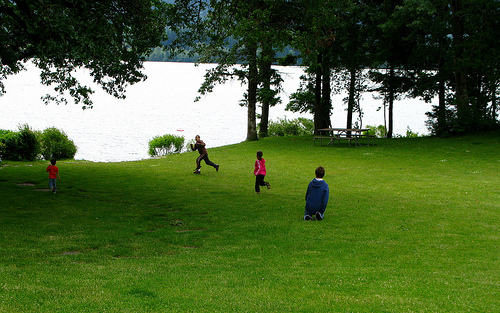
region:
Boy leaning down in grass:
[299, 157, 335, 229]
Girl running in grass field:
[246, 146, 279, 207]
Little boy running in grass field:
[39, 156, 70, 203]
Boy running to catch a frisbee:
[166, 124, 231, 188]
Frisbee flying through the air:
[171, 123, 190, 137]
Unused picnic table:
[310, 116, 379, 153]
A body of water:
[0, 53, 498, 163]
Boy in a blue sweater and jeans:
[300, 156, 330, 236]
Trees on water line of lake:
[202, 0, 498, 153]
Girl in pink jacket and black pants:
[240, 143, 290, 217]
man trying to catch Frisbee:
[158, 116, 226, 211]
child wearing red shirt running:
[33, 148, 89, 220]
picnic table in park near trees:
[305, 111, 417, 166]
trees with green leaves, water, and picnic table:
[217, 78, 455, 150]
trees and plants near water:
[8, 16, 133, 148]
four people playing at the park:
[22, 114, 359, 252]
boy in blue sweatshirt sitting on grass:
[298, 166, 343, 241]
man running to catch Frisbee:
[167, 113, 224, 190]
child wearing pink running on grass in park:
[241, 146, 273, 216]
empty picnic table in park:
[313, 113, 405, 160]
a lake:
[0, 38, 477, 150]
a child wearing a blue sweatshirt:
[287, 141, 342, 236]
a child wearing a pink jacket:
[243, 138, 288, 216]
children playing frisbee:
[158, 119, 299, 217]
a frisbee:
[168, 115, 200, 138]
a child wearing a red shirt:
[31, 131, 101, 208]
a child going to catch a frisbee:
[164, 116, 268, 222]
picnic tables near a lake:
[291, 105, 403, 160]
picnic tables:
[304, 104, 389, 159]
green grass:
[16, 137, 496, 282]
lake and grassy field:
[32, 26, 400, 282]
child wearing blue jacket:
[294, 155, 359, 241]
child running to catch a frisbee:
[160, 103, 229, 188]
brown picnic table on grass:
[301, 108, 401, 158]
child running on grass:
[38, 148, 80, 228]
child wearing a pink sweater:
[230, 134, 286, 211]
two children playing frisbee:
[168, 111, 283, 208]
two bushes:
[0, 120, 98, 185]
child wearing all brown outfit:
[131, 105, 236, 187]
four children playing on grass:
[0, 110, 385, 234]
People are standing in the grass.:
[42, 118, 350, 240]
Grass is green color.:
[325, 232, 433, 288]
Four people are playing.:
[25, 132, 353, 237]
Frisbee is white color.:
[162, 121, 187, 136]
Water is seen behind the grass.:
[43, 73, 191, 136]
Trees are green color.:
[271, 12, 481, 57]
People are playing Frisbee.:
[40, 122, 348, 225]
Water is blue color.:
[100, 105, 185, 126]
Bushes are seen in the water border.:
[0, 113, 83, 161]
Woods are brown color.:
[238, 59, 263, 139]